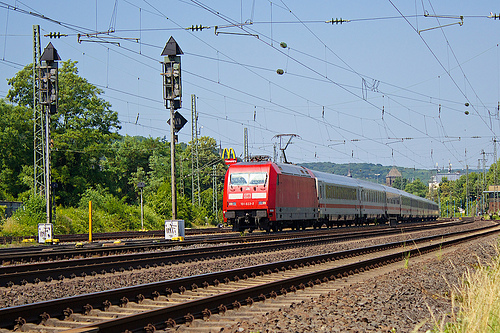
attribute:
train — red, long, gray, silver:
[224, 161, 442, 231]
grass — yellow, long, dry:
[460, 281, 489, 328]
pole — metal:
[160, 31, 189, 239]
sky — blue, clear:
[340, 31, 408, 61]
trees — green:
[77, 136, 147, 190]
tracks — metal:
[238, 244, 392, 284]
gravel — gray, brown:
[354, 287, 420, 320]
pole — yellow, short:
[82, 198, 107, 250]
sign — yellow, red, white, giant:
[218, 147, 244, 165]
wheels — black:
[259, 222, 335, 232]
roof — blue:
[428, 171, 464, 186]